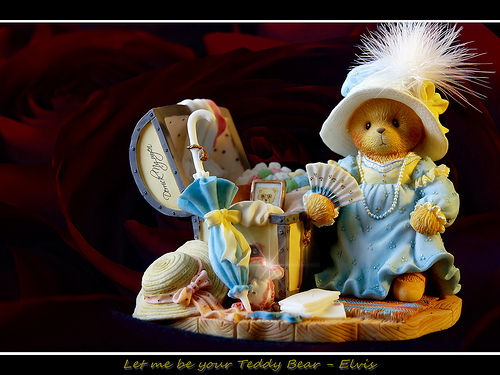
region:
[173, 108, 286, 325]
an umbrella on the figurine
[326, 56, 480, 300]
a teddy bear in a blue dress with pearls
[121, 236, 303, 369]
a hat and other things along the bottom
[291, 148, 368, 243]
the bear holds a fan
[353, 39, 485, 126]
fuzz and a yellow rose on the hat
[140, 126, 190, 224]
some writing on the chest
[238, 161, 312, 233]
a picture in the chest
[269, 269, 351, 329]
folded white cloth on floor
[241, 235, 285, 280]
a flash reflected off the figurine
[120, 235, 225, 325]
white straw hat with pink bow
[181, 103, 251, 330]
blue umbrella with white handle tied with yellow bow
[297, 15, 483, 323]
teddy bear in hat and blue dress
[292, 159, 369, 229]
hand of teddy bear holding fan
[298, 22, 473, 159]
teddy bear wearing white hat with fluffy pompon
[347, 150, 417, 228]
string of pearls on teddy bear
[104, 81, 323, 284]
trunk filled with teddy bear accessories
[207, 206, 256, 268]
yellow bow on toy umbrella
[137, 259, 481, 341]
wooden stand for teddy bear and accoutrements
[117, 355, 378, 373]
caption reading "let me be your teddy bear"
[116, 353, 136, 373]
the yellow letter L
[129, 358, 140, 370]
the yellow letter E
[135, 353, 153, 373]
the yellow letter t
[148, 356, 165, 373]
the yellow letter M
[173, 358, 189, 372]
the yellow letter B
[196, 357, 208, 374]
the yellow letter y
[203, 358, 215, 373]
the yellow letter O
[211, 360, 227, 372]
the yellow letter U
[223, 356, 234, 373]
the yellow letter R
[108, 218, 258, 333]
this is a hat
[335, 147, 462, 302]
Blue dress on a brown bean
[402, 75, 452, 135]
Yellow ribbon on a white hat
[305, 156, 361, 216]
Blue and white fan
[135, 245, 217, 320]
Tan hat with a polka dot ribbon and bow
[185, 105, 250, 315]
Blue umbrella with a yellow ribbon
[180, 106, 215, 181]
White handle on umbrella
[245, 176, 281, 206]
Picture of a bear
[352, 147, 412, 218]
White pearl necklass on bear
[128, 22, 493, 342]
a Cherished Teddy figurine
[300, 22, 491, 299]
a Cherished Teddy bear dressed up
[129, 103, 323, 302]
an open figural trunk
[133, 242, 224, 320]
an open figural straw hat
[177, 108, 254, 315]
a figural blue umbrella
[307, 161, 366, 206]
an open figural fan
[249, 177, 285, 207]
a figural framed photo of bear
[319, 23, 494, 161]
a large figural hat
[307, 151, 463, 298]
a blue figural dress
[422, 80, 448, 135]
a blue figural yellow bow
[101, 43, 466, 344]
toy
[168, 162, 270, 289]
blue toy umbrella on statue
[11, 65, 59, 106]
brown and red background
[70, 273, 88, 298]
brown and red background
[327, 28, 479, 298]
brown bear in dress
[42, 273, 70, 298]
brown and red background on wall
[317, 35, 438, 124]
white hat on bear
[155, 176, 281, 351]
blue and white umbrella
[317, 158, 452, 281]
bear has blue dress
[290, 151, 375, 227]
bear is holding fan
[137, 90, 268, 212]
white handle on umbrella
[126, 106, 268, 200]
treasure chest is open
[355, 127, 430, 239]
bear is wearing necklace